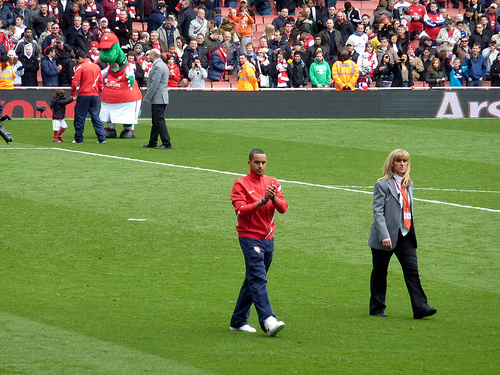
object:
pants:
[73, 96, 106, 142]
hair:
[377, 149, 411, 187]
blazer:
[368, 178, 418, 251]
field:
[0, 119, 500, 375]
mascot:
[99, 33, 143, 139]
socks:
[54, 128, 66, 140]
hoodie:
[50, 98, 74, 120]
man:
[228, 148, 285, 337]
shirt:
[230, 169, 288, 241]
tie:
[401, 178, 412, 229]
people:
[0, 0, 497, 87]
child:
[49, 89, 77, 143]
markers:
[0, 147, 500, 213]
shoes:
[229, 316, 285, 338]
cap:
[99, 33, 120, 49]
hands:
[265, 181, 277, 200]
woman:
[368, 149, 436, 320]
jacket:
[332, 59, 360, 91]